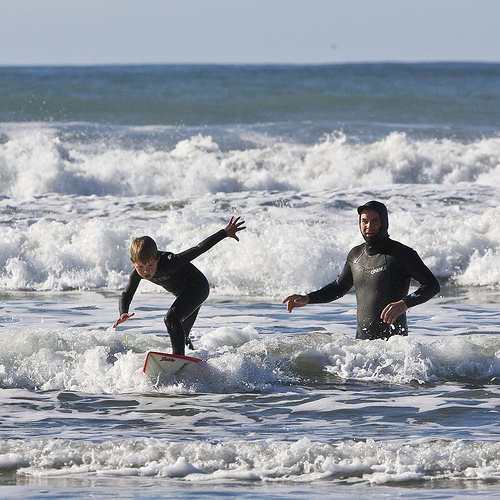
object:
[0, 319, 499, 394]
crashing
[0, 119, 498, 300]
crashing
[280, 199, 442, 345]
adult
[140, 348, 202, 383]
surfboard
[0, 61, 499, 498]
ocean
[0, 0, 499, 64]
sky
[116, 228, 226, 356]
wetsuit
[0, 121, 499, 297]
wave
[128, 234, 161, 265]
hair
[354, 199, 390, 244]
hat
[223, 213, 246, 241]
hand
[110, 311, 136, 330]
hand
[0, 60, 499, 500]
body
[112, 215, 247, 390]
surfing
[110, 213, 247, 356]
boy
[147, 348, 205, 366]
surfboard edge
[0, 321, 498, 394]
wave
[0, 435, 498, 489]
splashing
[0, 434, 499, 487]
wave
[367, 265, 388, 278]
letter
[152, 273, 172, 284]
letter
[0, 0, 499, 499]
scene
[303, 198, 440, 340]
wet suit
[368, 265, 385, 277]
logo